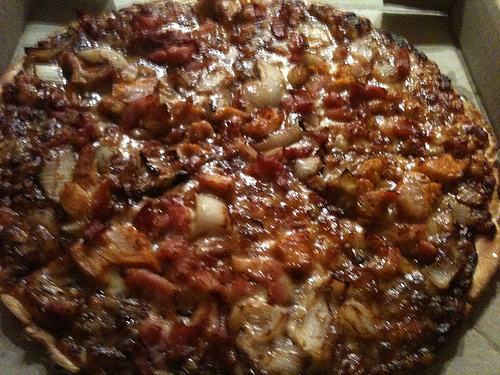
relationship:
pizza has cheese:
[5, 6, 491, 371] [240, 58, 286, 105]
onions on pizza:
[287, 277, 329, 357] [5, 6, 491, 371]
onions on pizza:
[228, 296, 328, 370] [5, 6, 491, 371]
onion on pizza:
[38, 142, 79, 201] [5, 6, 491, 371]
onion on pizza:
[28, 60, 63, 85] [5, 6, 491, 371]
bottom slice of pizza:
[12, 162, 457, 368] [5, 6, 491, 371]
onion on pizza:
[97, 138, 130, 170] [4, 105, 202, 290]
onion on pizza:
[38, 142, 79, 201] [4, 105, 202, 290]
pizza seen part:
[5, 6, 491, 371] [233, 285, 267, 330]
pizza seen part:
[5, 6, 491, 371] [101, 216, 124, 245]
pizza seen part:
[5, 6, 491, 371] [410, 156, 424, 172]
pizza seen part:
[5, 6, 491, 371] [9, 155, 443, 366]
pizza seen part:
[5, 6, 491, 371] [81, 107, 108, 132]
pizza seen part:
[5, 6, 491, 371] [248, 54, 280, 79]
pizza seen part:
[5, 6, 491, 371] [101, 124, 133, 165]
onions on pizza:
[287, 277, 329, 357] [281, 32, 472, 236]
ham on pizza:
[157, 124, 282, 255] [281, 32, 472, 236]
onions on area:
[287, 277, 329, 357] [224, 278, 344, 372]